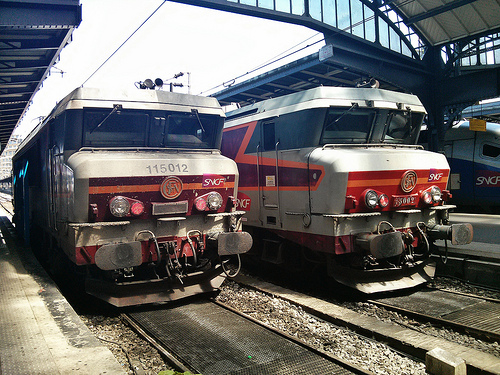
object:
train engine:
[7, 76, 254, 306]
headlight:
[109, 196, 146, 218]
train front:
[65, 87, 251, 308]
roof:
[222, 85, 427, 128]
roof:
[8, 85, 227, 152]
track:
[109, 295, 370, 375]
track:
[343, 282, 500, 340]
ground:
[474, 215, 499, 248]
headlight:
[360, 188, 389, 210]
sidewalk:
[0, 207, 130, 375]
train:
[218, 76, 474, 295]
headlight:
[420, 185, 442, 206]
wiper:
[90, 104, 121, 134]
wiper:
[191, 108, 206, 133]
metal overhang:
[0, 0, 83, 157]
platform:
[0, 207, 126, 375]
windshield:
[319, 105, 426, 147]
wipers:
[321, 102, 360, 130]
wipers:
[400, 103, 415, 137]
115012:
[146, 163, 189, 174]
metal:
[153, 283, 292, 375]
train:
[11, 86, 254, 309]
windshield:
[82, 106, 221, 149]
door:
[260, 116, 280, 210]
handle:
[256, 145, 264, 225]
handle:
[275, 141, 282, 226]